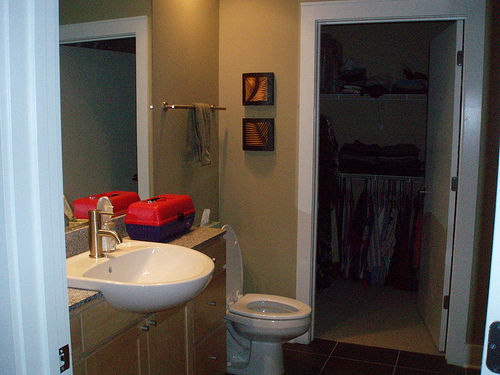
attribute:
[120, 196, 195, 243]
carryall — red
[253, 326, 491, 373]
tiles — dark brown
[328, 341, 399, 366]
tile — dark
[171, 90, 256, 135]
towel — hand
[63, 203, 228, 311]
counter top — marble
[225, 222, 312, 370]
toilet — white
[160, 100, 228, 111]
towel bar — metal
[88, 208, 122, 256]
fixtures — gold